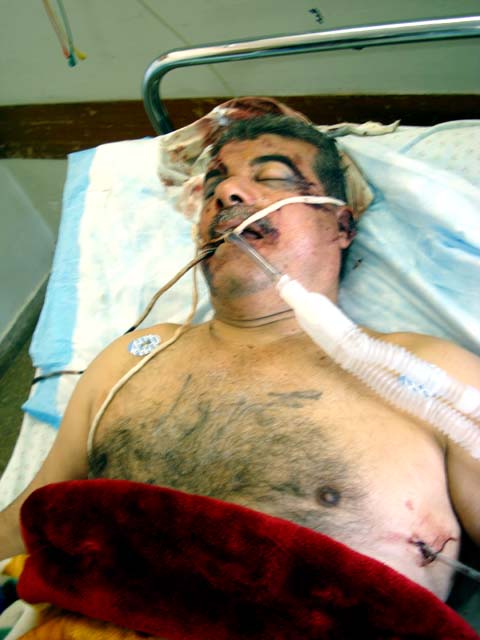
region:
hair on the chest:
[274, 438, 300, 457]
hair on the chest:
[274, 478, 289, 485]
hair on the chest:
[94, 447, 119, 464]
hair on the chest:
[204, 429, 230, 444]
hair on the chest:
[240, 478, 281, 507]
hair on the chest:
[281, 389, 312, 404]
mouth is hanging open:
[213, 221, 264, 247]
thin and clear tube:
[419, 541, 479, 585]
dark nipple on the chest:
[316, 482, 341, 513]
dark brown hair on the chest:
[78, 362, 361, 545]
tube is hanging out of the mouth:
[191, 216, 300, 280]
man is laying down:
[1, 98, 478, 638]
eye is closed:
[253, 157, 297, 194]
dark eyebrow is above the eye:
[251, 153, 301, 174]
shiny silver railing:
[121, 13, 478, 141]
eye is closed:
[257, 166, 294, 188]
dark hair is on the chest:
[81, 370, 370, 540]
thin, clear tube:
[412, 532, 479, 585]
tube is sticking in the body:
[399, 526, 479, 582]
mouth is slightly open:
[209, 214, 278, 249]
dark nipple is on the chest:
[313, 484, 340, 510]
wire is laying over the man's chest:
[83, 308, 198, 449]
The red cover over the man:
[10, 481, 472, 637]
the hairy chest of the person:
[71, 396, 378, 533]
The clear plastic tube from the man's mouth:
[215, 229, 478, 462]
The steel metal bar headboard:
[134, 15, 476, 100]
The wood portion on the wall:
[1, 90, 476, 143]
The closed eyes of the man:
[191, 164, 321, 195]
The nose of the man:
[208, 175, 249, 206]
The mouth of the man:
[200, 220, 269, 252]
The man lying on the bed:
[9, 150, 475, 614]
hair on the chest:
[199, 479, 214, 487]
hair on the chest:
[182, 411, 211, 430]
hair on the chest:
[109, 449, 126, 473]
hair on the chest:
[286, 396, 316, 404]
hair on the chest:
[210, 480, 237, 499]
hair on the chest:
[322, 454, 337, 471]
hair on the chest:
[148, 437, 172, 457]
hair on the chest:
[177, 456, 240, 490]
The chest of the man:
[116, 343, 465, 597]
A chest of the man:
[92, 336, 458, 586]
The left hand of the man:
[0, 365, 123, 551]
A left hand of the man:
[0, 397, 109, 543]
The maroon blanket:
[25, 478, 457, 627]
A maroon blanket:
[5, 478, 434, 623]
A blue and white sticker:
[123, 327, 174, 361]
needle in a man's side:
[424, 548, 476, 577]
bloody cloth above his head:
[153, 92, 377, 221]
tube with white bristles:
[230, 234, 477, 444]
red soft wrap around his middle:
[18, 477, 474, 638]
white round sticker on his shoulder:
[127, 334, 161, 355]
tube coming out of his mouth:
[121, 247, 213, 334]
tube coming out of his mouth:
[84, 236, 236, 467]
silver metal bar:
[140, 11, 475, 142]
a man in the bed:
[145, 119, 467, 368]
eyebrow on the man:
[261, 150, 298, 191]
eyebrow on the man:
[172, 123, 244, 200]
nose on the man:
[218, 161, 256, 213]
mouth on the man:
[221, 205, 252, 252]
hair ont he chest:
[146, 393, 236, 474]